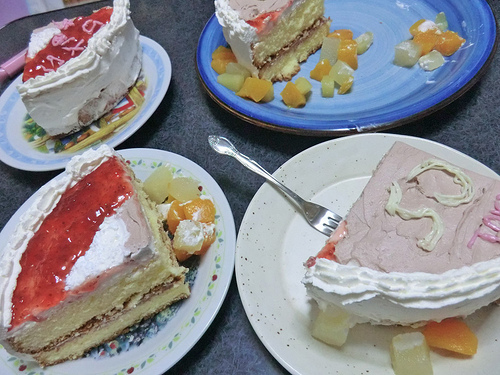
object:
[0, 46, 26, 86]
object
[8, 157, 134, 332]
sauce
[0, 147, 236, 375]
plate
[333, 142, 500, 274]
icing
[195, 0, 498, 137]
plate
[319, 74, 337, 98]
peach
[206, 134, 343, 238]
fork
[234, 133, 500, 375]
plate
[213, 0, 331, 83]
desert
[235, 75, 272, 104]
fruit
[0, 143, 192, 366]
cake